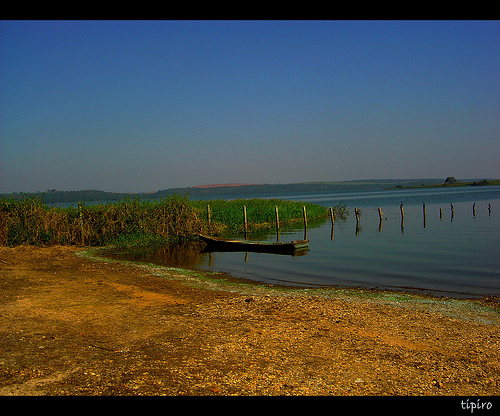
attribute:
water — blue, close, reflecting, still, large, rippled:
[334, 228, 418, 271]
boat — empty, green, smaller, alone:
[208, 229, 313, 261]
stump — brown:
[371, 206, 393, 226]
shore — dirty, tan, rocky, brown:
[90, 274, 268, 365]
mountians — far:
[83, 178, 131, 203]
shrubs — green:
[85, 208, 130, 227]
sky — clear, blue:
[214, 37, 259, 69]